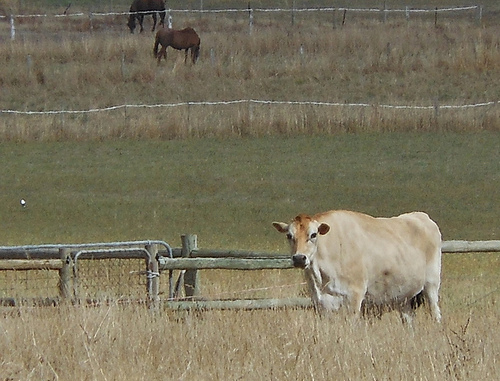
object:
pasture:
[7, 10, 495, 378]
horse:
[123, 1, 169, 34]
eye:
[310, 232, 317, 238]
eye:
[286, 233, 293, 240]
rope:
[0, 93, 500, 114]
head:
[271, 214, 331, 270]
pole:
[247, 0, 252, 39]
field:
[6, 0, 498, 379]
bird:
[20, 196, 27, 208]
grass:
[0, 127, 498, 251]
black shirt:
[157, 26, 200, 49]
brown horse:
[153, 27, 201, 65]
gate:
[73, 241, 160, 318]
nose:
[292, 253, 307, 263]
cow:
[271, 208, 446, 326]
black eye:
[310, 232, 318, 239]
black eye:
[285, 232, 292, 240]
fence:
[0, 238, 500, 314]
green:
[19, 154, 230, 229]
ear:
[270, 221, 288, 233]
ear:
[316, 222, 331, 237]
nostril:
[292, 255, 307, 261]